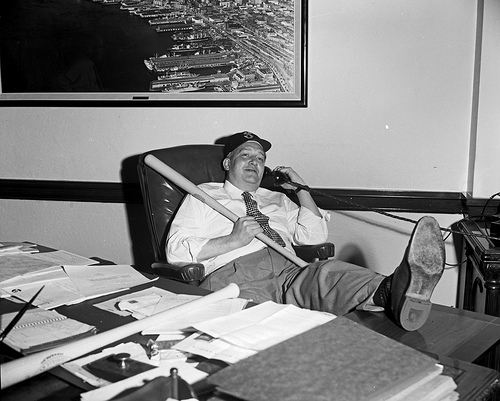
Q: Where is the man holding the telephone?
A: In his left hand.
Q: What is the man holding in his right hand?
A: A baseball bat.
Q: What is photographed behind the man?
A: A harbor.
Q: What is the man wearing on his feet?
A: Boots.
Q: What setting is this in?
A: An office.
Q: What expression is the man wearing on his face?
A: Light joy.